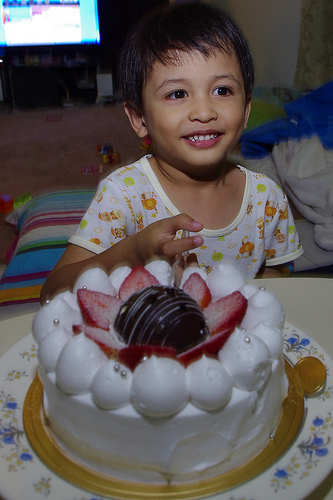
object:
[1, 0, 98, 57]
television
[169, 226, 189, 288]
knife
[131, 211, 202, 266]
hand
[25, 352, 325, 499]
plastic plate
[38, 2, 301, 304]
boy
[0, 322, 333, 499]
cake tray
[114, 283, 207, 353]
ball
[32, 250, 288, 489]
wall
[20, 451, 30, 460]
blue flowers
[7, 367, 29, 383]
yellow flowers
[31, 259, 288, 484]
icing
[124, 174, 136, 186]
designs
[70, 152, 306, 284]
shirt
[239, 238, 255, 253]
shirt mushrooms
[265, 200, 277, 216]
shirt mushrooms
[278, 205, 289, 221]
shirt mushrooms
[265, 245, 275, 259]
shirt mushrooms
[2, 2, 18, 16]
lcd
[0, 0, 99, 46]
screen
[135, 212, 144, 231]
flower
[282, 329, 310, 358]
fence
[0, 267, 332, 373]
table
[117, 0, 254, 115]
hair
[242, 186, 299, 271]
linens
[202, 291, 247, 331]
strawberries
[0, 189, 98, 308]
pillow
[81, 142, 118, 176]
toys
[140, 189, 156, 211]
design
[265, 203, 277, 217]
design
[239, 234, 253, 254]
design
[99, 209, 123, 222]
design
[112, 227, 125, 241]
design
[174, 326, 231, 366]
strawberry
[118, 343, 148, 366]
strawberry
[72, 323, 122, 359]
strawberry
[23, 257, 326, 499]
cake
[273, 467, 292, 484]
flower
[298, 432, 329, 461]
flower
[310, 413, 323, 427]
flower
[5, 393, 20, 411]
flower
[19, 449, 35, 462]
flower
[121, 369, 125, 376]
beads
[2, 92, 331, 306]
floor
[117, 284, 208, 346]
candy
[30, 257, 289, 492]
frosting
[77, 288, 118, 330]
strawberries